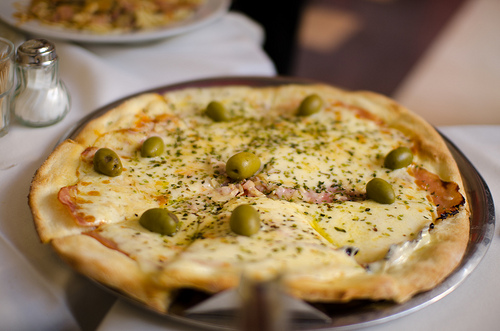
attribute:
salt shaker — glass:
[2, 24, 71, 118]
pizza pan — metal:
[16, 72, 485, 319]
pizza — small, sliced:
[101, 114, 432, 275]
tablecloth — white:
[128, 48, 208, 80]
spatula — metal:
[174, 276, 347, 326]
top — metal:
[10, 37, 58, 72]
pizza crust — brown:
[339, 81, 448, 150]